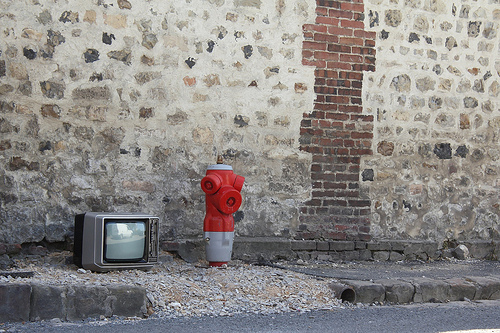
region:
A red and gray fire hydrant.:
[198, 161, 245, 265]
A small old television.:
[71, 209, 161, 275]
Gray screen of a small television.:
[102, 221, 147, 263]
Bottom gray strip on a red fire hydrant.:
[202, 228, 234, 263]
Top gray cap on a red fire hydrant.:
[205, 162, 234, 172]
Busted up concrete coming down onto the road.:
[146, 285, 349, 314]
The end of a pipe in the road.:
[339, 286, 358, 305]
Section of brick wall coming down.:
[297, 0, 378, 245]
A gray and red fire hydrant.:
[198, 164, 243, 265]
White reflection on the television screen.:
[114, 221, 133, 242]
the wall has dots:
[123, 37, 308, 134]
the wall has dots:
[106, 32, 227, 129]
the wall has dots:
[160, 48, 261, 163]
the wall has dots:
[162, 82, 306, 174]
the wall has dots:
[180, 38, 277, 98]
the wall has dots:
[135, 15, 239, 107]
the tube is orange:
[193, 150, 255, 291]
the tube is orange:
[196, 140, 294, 331]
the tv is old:
[69, 181, 209, 312]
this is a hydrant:
[196, 159, 248, 266]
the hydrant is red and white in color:
[196, 157, 251, 262]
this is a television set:
[72, 207, 170, 272]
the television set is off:
[77, 205, 167, 270]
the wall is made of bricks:
[321, 25, 358, 75]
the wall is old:
[312, 39, 359, 124]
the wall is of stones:
[61, 37, 261, 149]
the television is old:
[75, 212, 163, 274]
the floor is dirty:
[170, 266, 289, 311]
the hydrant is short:
[195, 155, 249, 260]